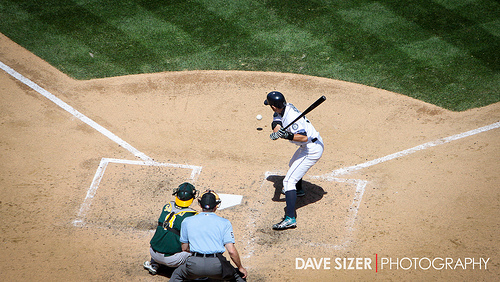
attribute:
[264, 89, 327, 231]
man — ready, on offense, ready to swing, baseball player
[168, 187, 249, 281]
umpire — crouching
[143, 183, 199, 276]
player — squatting, catcher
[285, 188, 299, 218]
sock — blue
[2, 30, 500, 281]
sand — red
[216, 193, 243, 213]
home plate — white, triangular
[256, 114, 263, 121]
baseball — flying, white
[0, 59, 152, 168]
line — white, third base line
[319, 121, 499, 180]
line — white, first base line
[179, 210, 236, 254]
shirt — blue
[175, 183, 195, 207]
hat — yellow, backwards, green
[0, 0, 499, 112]
grass — cut, infield grass, green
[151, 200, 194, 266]
uniform — green, yellow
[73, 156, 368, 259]
batter's box — used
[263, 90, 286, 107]
helmet — black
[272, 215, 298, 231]
shoe — blue, baseball shoe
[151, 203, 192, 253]
shirt — green